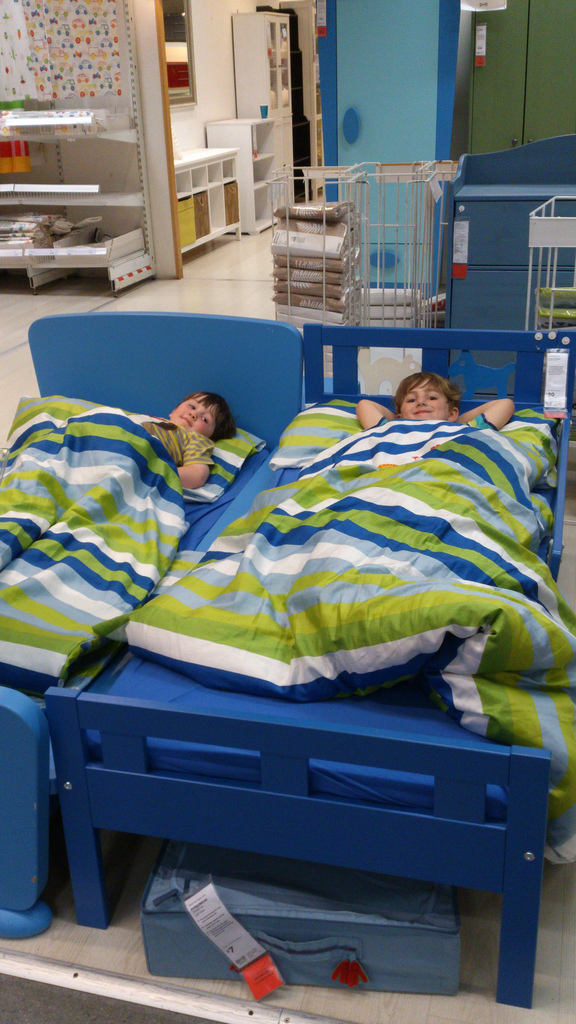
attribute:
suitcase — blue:
[101, 876, 491, 1000]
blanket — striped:
[139, 424, 572, 765]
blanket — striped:
[125, 412, 569, 806]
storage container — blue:
[116, 841, 489, 989]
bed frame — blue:
[41, 679, 552, 976]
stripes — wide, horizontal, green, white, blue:
[180, 414, 541, 636]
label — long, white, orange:
[444, 216, 473, 281]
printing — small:
[452, 215, 466, 257]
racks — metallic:
[260, 159, 456, 330]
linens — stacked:
[272, 201, 342, 329]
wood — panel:
[421, 767, 486, 831]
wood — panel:
[250, 746, 315, 799]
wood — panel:
[73, 691, 543, 789]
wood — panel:
[101, 768, 500, 876]